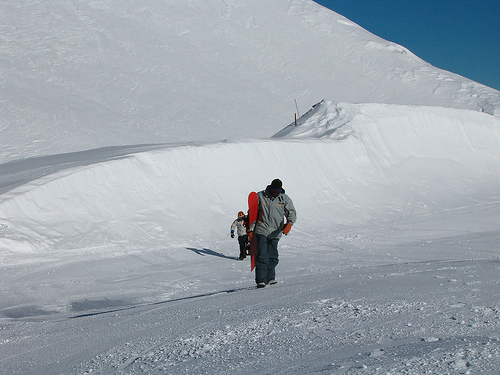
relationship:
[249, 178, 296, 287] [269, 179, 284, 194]
man wearing baseball cap on his head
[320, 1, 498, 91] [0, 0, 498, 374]
blues sky a clear snow day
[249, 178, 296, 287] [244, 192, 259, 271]
man has a red snowboard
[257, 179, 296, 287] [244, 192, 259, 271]
snowboarder carrying a red snowboard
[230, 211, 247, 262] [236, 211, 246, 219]
man wearing a yellow helmet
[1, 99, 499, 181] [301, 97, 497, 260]
ridge formed from snow build up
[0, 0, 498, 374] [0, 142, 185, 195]
sunlight angle creates shadows in the snow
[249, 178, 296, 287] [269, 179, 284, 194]
man has a black cap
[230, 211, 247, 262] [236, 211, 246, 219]
snowboarder has a ski cap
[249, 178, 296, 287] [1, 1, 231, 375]
snowboarder walking in snow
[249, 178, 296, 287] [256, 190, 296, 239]
man has a silver ski jacket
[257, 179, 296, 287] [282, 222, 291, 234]
snowboarder has red ski gloves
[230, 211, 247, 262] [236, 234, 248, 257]
snowboarder has black ski pants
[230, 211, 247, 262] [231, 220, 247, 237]
snowboarder has a white ski jacket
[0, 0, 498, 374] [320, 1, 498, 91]
sunny day and blue sky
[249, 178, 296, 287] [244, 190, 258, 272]
man carrying red snowboard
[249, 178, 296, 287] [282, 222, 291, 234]
man with red gloves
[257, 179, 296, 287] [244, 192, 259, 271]
man with a red snowboard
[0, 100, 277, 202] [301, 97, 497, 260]
slope formed from snow drifts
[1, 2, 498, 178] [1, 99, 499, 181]
snow formed from snow drifts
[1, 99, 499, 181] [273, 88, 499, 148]
snow drifts form snow ridges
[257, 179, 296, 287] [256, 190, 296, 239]
snowboarder wearing a ski jacket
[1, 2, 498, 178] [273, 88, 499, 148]
snow formed a snow bank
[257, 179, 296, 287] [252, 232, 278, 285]
snowboarder has grey ski pants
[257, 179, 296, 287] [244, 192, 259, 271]
snowboarder has a red snowboard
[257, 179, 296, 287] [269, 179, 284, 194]
snowboarder has a black cap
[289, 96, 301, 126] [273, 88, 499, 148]
markers are for marking snow drifts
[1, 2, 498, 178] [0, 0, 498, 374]
snow ha different texture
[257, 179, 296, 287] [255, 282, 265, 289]
snowboarder walking with shoes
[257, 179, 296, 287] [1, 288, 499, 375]
snowboarder walking to the slope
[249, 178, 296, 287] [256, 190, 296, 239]
snowboareder has a grey ski jacket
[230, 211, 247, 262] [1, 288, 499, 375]
snowboarder walking up slope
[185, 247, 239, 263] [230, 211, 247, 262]
shadow formed behind snowboarder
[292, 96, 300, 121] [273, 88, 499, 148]
snow markers mark snow drifts